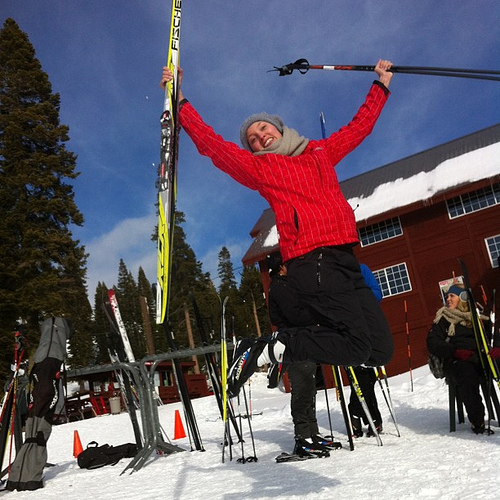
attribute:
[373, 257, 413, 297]
window — white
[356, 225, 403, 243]
window — white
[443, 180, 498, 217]
window — white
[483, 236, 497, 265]
window — white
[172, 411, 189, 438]
traffic cone — orange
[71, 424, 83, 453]
traffic cone — orange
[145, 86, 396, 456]
woman — blonde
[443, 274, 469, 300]
headband — blue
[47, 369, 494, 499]
snow — white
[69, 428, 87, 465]
orange cone — red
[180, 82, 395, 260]
jacket — bright red, bright, red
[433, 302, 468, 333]
scarf — gray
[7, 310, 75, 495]
bag — gray, black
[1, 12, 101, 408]
pine tree — tall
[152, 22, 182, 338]
snow board — yellow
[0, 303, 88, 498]
ski — gray, green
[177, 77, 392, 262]
snow jacket — red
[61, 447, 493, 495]
snow — white, powdery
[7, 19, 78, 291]
tree — big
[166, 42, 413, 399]
skier — jumping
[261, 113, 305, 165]
scarf — grey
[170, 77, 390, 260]
coat — red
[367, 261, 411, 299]
cross bars — white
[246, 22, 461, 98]
stick — ski